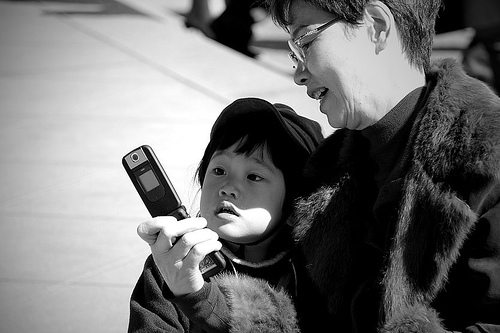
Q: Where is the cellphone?
A: In the lady's hand.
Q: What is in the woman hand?
A: A cell phone.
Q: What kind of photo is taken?
A: Black and white.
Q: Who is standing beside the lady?
A: A boy.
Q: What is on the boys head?
A: A hat.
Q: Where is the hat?
A: Boys head.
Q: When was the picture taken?
A: Sunny day.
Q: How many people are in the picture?
A: 2.